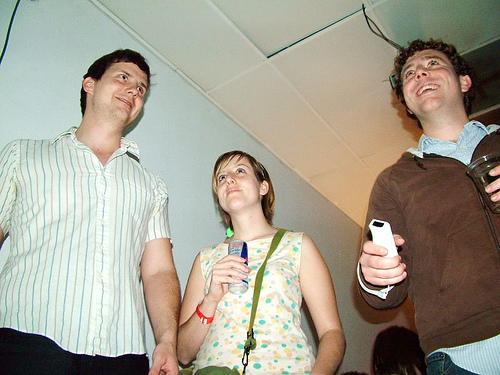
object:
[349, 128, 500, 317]
jacket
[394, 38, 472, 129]
hair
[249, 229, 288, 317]
strap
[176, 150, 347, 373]
girl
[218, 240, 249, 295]
can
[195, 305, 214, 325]
bracelet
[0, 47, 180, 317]
man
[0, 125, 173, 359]
shirt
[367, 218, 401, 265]
controller